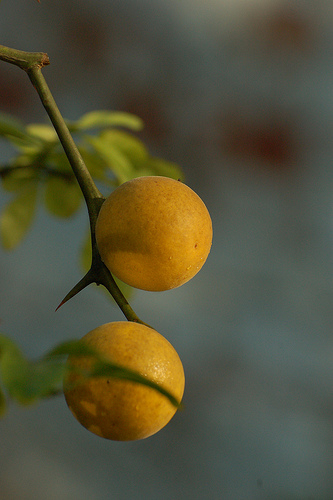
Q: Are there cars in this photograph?
A: No, there are no cars.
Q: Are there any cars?
A: No, there are no cars.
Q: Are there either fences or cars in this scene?
A: No, there are no cars or fences.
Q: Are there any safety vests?
A: No, there are no safety vests.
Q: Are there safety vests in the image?
A: No, there are no safety vests.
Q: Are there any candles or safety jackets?
A: No, there are no safety jackets or candles.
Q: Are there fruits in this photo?
A: Yes, there is a fruit.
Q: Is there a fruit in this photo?
A: Yes, there is a fruit.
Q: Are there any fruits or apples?
A: Yes, there is a fruit.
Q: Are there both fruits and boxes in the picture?
A: No, there is a fruit but no boxes.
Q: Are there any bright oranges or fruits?
A: Yes, there is a bright fruit.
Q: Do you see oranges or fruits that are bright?
A: Yes, the fruit is bright.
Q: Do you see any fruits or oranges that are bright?
A: Yes, the fruit is bright.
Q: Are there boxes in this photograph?
A: No, there are no boxes.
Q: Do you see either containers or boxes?
A: No, there are no boxes or containers.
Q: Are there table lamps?
A: No, there are no table lamps.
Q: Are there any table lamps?
A: No, there are no table lamps.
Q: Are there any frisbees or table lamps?
A: No, there are no table lamps or frisbees.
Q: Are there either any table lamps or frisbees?
A: No, there are no table lamps or frisbees.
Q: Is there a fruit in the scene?
A: Yes, there is a fruit.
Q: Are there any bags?
A: No, there are no bags.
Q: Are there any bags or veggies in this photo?
A: No, there are no bags or veggies.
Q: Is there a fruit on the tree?
A: Yes, there is a fruit on the tree.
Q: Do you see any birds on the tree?
A: No, there is a fruit on the tree.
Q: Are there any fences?
A: No, there are no fences.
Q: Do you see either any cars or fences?
A: No, there are no fences or cars.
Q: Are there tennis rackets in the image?
A: No, there are no tennis rackets.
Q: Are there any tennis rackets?
A: No, there are no tennis rackets.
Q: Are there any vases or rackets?
A: No, there are no rackets or vases.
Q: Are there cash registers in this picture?
A: No, there are no cash registers.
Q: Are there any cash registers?
A: No, there are no cash registers.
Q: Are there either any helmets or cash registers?
A: No, there are no cash registers or helmets.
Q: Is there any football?
A: No, there are no footballs.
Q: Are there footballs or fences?
A: No, there are no footballs or fences.